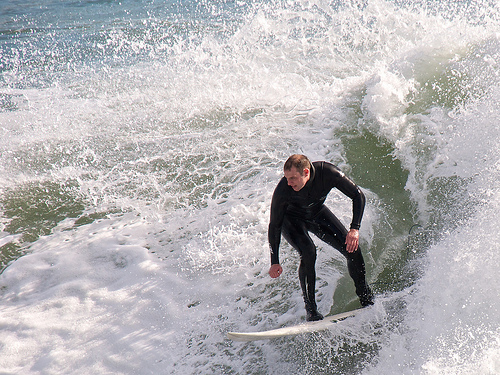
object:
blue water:
[0, 0, 220, 85]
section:
[2, 1, 209, 40]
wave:
[0, 0, 498, 374]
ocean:
[0, 0, 499, 374]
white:
[433, 308, 494, 373]